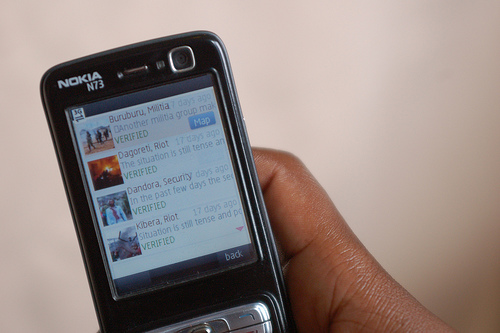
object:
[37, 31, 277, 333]
cell phone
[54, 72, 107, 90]
nokia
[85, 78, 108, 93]
n73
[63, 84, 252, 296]
screen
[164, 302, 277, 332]
keypad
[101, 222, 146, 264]
pictures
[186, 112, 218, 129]
square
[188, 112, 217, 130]
map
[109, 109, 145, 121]
buruburu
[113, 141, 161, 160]
dagoreti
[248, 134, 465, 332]
person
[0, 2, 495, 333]
wall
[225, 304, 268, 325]
button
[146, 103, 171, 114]
militia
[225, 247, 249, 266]
icon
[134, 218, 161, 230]
kibera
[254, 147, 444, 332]
hand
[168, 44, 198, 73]
camera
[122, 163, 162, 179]
word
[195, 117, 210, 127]
lettering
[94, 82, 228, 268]
news feed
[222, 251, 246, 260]
lettering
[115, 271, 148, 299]
icon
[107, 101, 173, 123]
name